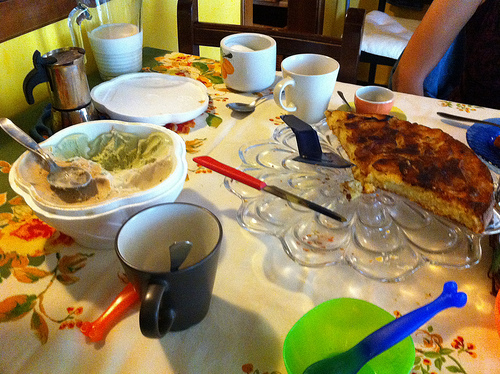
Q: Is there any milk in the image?
A: Yes, there is milk.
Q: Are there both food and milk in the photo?
A: Yes, there are both milk and food.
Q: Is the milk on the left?
A: Yes, the milk is on the left of the image.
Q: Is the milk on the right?
A: No, the milk is on the left of the image.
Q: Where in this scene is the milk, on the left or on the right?
A: The milk is on the left of the image.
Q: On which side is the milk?
A: The milk is on the left of the image.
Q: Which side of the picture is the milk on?
A: The milk is on the left of the image.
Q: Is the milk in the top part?
A: Yes, the milk is in the top of the image.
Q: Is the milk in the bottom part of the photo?
A: No, the milk is in the top of the image.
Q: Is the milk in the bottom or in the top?
A: The milk is in the top of the image.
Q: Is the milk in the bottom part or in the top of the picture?
A: The milk is in the top of the image.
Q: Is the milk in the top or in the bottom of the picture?
A: The milk is in the top of the image.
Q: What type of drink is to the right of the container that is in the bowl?
A: The drink is milk.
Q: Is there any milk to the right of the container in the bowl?
A: Yes, there is milk to the right of the container.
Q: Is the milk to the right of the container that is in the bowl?
A: Yes, the milk is to the right of the container.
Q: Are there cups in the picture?
A: Yes, there is a cup.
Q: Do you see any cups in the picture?
A: Yes, there is a cup.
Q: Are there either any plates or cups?
A: Yes, there is a cup.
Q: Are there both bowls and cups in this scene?
A: Yes, there are both a cup and a bowl.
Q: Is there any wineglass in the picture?
A: No, there are no wine glasses.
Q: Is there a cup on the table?
A: Yes, there is a cup on the table.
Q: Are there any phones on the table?
A: No, there is a cup on the table.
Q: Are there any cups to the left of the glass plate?
A: Yes, there is a cup to the left of the plate.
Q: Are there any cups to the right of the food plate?
A: No, the cup is to the left of the plate.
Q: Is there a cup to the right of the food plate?
A: No, the cup is to the left of the plate.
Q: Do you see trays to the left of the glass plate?
A: No, there is a cup to the left of the plate.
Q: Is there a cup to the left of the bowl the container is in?
A: Yes, there is a cup to the left of the bowl.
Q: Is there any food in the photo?
A: Yes, there is food.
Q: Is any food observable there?
A: Yes, there is food.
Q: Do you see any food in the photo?
A: Yes, there is food.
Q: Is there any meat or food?
A: Yes, there is food.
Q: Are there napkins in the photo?
A: No, there are no napkins.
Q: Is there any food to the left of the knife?
A: Yes, there is food to the left of the knife.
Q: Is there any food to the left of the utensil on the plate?
A: Yes, there is food to the left of the knife.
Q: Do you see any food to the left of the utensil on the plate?
A: Yes, there is food to the left of the knife.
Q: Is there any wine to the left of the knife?
A: No, there is food to the left of the knife.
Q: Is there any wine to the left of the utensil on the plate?
A: No, there is food to the left of the knife.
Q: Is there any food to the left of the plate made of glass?
A: Yes, there is food to the left of the plate.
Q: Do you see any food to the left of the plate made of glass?
A: Yes, there is food to the left of the plate.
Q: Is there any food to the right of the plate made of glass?
A: No, the food is to the left of the plate.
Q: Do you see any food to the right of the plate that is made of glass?
A: No, the food is to the left of the plate.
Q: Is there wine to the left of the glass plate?
A: No, there is food to the left of the plate.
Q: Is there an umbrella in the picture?
A: No, there are no umbrellas.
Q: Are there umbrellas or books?
A: No, there are no umbrellas or books.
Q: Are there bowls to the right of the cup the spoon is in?
A: Yes, there is a bowl to the right of the cup.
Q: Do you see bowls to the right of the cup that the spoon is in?
A: Yes, there is a bowl to the right of the cup.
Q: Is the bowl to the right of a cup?
A: Yes, the bowl is to the right of a cup.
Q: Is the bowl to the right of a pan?
A: No, the bowl is to the right of a cup.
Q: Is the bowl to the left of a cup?
A: No, the bowl is to the right of a cup.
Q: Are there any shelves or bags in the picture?
A: No, there are no bags or shelves.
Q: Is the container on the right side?
A: No, the container is on the left of the image.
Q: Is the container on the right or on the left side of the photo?
A: The container is on the left of the image.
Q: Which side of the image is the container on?
A: The container is on the left of the image.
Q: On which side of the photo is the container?
A: The container is on the left of the image.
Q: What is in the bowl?
A: The container is in the bowl.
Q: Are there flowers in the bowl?
A: No, there is a container in the bowl.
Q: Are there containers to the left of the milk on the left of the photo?
A: Yes, there is a container to the left of the milk.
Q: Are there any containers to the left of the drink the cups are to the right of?
A: Yes, there is a container to the left of the milk.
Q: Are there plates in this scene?
A: Yes, there is a plate.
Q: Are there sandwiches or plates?
A: Yes, there is a plate.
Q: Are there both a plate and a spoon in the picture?
A: Yes, there are both a plate and a spoon.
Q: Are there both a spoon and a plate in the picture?
A: Yes, there are both a plate and a spoon.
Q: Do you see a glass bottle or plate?
A: Yes, there is a glass plate.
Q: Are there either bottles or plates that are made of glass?
A: Yes, the plate is made of glass.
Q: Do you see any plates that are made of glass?
A: Yes, there is a plate that is made of glass.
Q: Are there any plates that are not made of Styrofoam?
A: Yes, there is a plate that is made of glass.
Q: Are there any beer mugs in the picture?
A: No, there are no beer mugs.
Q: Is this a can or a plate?
A: This is a plate.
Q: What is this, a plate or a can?
A: This is a plate.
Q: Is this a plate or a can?
A: This is a plate.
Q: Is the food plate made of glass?
A: Yes, the plate is made of glass.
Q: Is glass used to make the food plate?
A: Yes, the plate is made of glass.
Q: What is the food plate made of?
A: The plate is made of glass.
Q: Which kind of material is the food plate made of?
A: The plate is made of glass.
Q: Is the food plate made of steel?
A: No, the plate is made of glass.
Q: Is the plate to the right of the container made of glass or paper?
A: The plate is made of glass.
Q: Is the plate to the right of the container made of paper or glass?
A: The plate is made of glass.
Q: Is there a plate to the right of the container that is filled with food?
A: Yes, there is a plate to the right of the container.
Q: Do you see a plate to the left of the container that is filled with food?
A: No, the plate is to the right of the container.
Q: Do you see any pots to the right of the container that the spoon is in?
A: No, there is a plate to the right of the container.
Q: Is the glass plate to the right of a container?
A: Yes, the plate is to the right of a container.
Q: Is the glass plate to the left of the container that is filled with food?
A: No, the plate is to the right of the container.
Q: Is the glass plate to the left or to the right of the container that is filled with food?
A: The plate is to the right of the container.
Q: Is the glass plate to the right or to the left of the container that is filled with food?
A: The plate is to the right of the container.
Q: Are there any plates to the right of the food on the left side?
A: Yes, there is a plate to the right of the food.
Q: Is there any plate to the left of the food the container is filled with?
A: No, the plate is to the right of the food.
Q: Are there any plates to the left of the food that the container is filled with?
A: No, the plate is to the right of the food.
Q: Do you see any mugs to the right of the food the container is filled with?
A: No, there is a plate to the right of the food.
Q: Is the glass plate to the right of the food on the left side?
A: Yes, the plate is to the right of the food.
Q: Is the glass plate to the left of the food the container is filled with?
A: No, the plate is to the right of the food.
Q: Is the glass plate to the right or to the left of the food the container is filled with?
A: The plate is to the right of the food.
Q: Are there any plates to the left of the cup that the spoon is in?
A: No, the plate is to the right of the cup.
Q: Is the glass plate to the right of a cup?
A: Yes, the plate is to the right of a cup.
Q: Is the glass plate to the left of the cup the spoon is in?
A: No, the plate is to the right of the cup.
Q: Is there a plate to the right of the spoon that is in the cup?
A: Yes, there is a plate to the right of the spoon.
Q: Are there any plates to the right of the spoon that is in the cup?
A: Yes, there is a plate to the right of the spoon.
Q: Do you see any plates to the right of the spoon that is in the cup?
A: Yes, there is a plate to the right of the spoon.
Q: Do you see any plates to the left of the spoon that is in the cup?
A: No, the plate is to the right of the spoon.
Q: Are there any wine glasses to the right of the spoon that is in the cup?
A: No, there is a plate to the right of the spoon.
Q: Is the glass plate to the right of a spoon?
A: Yes, the plate is to the right of a spoon.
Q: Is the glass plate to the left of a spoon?
A: No, the plate is to the right of a spoon.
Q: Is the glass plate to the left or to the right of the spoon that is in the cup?
A: The plate is to the right of the spoon.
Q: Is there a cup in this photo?
A: Yes, there is a cup.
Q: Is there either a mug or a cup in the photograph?
A: Yes, there is a cup.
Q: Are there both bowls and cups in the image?
A: Yes, there are both a cup and a bowl.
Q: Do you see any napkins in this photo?
A: No, there are no napkins.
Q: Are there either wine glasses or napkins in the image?
A: No, there are no napkins or wine glasses.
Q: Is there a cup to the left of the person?
A: Yes, there is a cup to the left of the person.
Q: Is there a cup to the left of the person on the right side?
A: Yes, there is a cup to the left of the person.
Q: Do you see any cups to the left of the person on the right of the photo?
A: Yes, there is a cup to the left of the person.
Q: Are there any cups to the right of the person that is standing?
A: No, the cup is to the left of the person.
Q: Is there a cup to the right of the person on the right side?
A: No, the cup is to the left of the person.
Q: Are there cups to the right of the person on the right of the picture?
A: No, the cup is to the left of the person.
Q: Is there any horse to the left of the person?
A: No, there is a cup to the left of the person.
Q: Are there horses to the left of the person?
A: No, there is a cup to the left of the person.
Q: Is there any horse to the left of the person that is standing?
A: No, there is a cup to the left of the person.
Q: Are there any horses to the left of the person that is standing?
A: No, there is a cup to the left of the person.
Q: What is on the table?
A: The cup is on the table.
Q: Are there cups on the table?
A: Yes, there is a cup on the table.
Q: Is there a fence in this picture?
A: No, there are no fences.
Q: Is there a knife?
A: Yes, there is a knife.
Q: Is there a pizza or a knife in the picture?
A: Yes, there is a knife.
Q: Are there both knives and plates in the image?
A: Yes, there are both a knife and a plate.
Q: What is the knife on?
A: The knife is on the plate.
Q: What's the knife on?
A: The knife is on the plate.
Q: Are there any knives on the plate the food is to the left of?
A: Yes, there is a knife on the plate.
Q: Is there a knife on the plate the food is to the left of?
A: Yes, there is a knife on the plate.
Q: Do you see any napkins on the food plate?
A: No, there is a knife on the plate.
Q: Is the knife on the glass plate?
A: Yes, the knife is on the plate.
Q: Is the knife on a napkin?
A: No, the knife is on the plate.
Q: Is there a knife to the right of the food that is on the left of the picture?
A: Yes, there is a knife to the right of the food.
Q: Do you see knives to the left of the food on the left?
A: No, the knife is to the right of the food.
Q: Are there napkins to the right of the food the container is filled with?
A: No, there is a knife to the right of the food.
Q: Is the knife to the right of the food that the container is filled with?
A: Yes, the knife is to the right of the food.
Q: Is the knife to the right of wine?
A: No, the knife is to the right of the food.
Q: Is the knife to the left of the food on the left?
A: No, the knife is to the right of the food.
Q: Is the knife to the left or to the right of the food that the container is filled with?
A: The knife is to the right of the food.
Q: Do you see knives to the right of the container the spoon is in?
A: Yes, there is a knife to the right of the container.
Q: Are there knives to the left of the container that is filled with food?
A: No, the knife is to the right of the container.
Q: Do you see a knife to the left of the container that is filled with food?
A: No, the knife is to the right of the container.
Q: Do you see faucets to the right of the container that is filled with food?
A: No, there is a knife to the right of the container.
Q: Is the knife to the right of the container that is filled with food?
A: Yes, the knife is to the right of the container.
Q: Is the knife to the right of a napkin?
A: No, the knife is to the right of the container.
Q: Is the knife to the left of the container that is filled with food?
A: No, the knife is to the right of the container.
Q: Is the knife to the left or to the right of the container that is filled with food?
A: The knife is to the right of the container.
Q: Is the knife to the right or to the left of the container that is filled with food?
A: The knife is to the right of the container.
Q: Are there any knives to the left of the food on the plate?
A: Yes, there is a knife to the left of the food.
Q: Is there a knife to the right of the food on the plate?
A: No, the knife is to the left of the food.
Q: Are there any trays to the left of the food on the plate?
A: No, there is a knife to the left of the food.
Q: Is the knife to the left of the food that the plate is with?
A: Yes, the knife is to the left of the food.